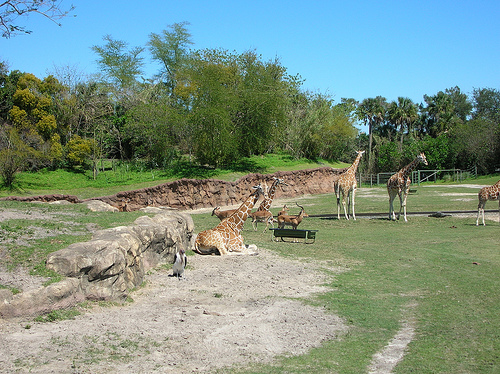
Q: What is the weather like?
A: It is clear.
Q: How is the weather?
A: It is clear.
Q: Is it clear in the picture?
A: Yes, it is clear.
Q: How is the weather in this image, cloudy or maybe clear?
A: It is clear.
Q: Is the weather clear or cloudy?
A: It is clear.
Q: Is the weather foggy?
A: No, it is clear.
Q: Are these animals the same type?
A: Yes, all the animals are giraffes.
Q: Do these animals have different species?
A: No, all the animals are giraffes.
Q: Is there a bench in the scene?
A: Yes, there is a bench.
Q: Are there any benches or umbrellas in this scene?
A: Yes, there is a bench.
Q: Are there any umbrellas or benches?
A: Yes, there is a bench.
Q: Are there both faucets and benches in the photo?
A: No, there is a bench but no faucets.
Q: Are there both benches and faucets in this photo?
A: No, there is a bench but no faucets.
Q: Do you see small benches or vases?
A: Yes, there is a small bench.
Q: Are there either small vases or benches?
A: Yes, there is a small bench.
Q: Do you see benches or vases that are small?
A: Yes, the bench is small.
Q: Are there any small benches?
A: Yes, there is a small bench.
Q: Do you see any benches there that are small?
A: Yes, there is a bench that is small.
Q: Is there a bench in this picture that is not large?
A: Yes, there is a small bench.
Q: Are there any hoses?
A: No, there are no hoses.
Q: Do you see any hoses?
A: No, there are no hoses.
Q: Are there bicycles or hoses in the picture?
A: No, there are no hoses or bicycles.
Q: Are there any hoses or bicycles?
A: No, there are no hoses or bicycles.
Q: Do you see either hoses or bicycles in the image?
A: No, there are no hoses or bicycles.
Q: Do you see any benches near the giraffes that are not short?
A: Yes, there is a bench near the giraffes.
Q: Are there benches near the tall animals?
A: Yes, there is a bench near the giraffes.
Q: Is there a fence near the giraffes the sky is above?
A: No, there is a bench near the giraffes.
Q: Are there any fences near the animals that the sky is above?
A: No, there is a bench near the giraffes.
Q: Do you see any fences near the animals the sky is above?
A: No, there is a bench near the giraffes.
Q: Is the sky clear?
A: Yes, the sky is clear.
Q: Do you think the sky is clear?
A: Yes, the sky is clear.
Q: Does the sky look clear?
A: Yes, the sky is clear.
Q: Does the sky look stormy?
A: No, the sky is clear.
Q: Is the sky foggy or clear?
A: The sky is clear.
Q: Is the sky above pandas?
A: No, the sky is above the giraffes.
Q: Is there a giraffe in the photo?
A: Yes, there are giraffes.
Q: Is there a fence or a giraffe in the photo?
A: Yes, there are giraffes.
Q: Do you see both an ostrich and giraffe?
A: No, there are giraffes but no ostriches.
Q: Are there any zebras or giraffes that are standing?
A: Yes, the giraffes are standing.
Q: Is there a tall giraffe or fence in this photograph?
A: Yes, there are tall giraffes.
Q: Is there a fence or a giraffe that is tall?
A: Yes, the giraffes are tall.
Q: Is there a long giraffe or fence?
A: Yes, there are long giraffes.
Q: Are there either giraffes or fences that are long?
A: Yes, the giraffes are long.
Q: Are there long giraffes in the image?
A: Yes, there are long giraffes.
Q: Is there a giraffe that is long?
A: Yes, there are giraffes that are long.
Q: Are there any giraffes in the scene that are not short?
A: Yes, there are long giraffes.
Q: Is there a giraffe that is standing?
A: Yes, there are giraffes that are standing.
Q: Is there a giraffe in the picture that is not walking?
A: Yes, there are giraffes that are standing.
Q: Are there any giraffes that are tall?
A: Yes, there are tall giraffes.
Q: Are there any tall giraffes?
A: Yes, there are tall giraffes.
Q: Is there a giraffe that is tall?
A: Yes, there are giraffes that are tall.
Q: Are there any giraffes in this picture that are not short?
A: Yes, there are tall giraffes.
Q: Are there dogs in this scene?
A: No, there are no dogs.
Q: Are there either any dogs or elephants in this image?
A: No, there are no dogs or elephants.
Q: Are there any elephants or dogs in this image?
A: No, there are no dogs or elephants.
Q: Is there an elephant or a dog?
A: No, there are no dogs or elephants.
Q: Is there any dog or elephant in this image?
A: No, there are no dogs or elephants.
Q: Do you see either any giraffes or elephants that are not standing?
A: No, there are giraffes but they are standing.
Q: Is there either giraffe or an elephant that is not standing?
A: No, there are giraffes but they are standing.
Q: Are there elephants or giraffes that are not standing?
A: No, there are giraffes but they are standing.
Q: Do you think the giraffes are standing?
A: Yes, the giraffes are standing.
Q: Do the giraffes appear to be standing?
A: Yes, the giraffes are standing.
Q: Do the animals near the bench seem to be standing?
A: Yes, the giraffes are standing.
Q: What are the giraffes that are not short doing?
A: The giraffes are standing.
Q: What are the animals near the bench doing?
A: The giraffes are standing.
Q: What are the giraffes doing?
A: The giraffes are standing.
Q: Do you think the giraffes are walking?
A: No, the giraffes are standing.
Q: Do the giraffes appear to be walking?
A: No, the giraffes are standing.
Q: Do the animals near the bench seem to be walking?
A: No, the giraffes are standing.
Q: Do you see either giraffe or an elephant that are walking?
A: No, there are giraffes but they are standing.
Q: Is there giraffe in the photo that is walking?
A: No, there are giraffes but they are standing.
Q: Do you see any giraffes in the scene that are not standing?
A: No, there are giraffes but they are standing.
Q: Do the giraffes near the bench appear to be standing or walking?
A: The giraffes are standing.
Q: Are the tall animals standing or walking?
A: The giraffes are standing.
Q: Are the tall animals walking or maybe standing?
A: The giraffes are standing.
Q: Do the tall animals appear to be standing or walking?
A: The giraffes are standing.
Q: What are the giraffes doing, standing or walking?
A: The giraffes are standing.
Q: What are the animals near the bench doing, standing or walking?
A: The giraffes are standing.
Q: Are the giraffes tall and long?
A: Yes, the giraffes are tall and long.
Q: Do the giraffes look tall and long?
A: Yes, the giraffes are tall and long.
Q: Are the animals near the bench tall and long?
A: Yes, the giraffes are tall and long.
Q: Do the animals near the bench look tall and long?
A: Yes, the giraffes are tall and long.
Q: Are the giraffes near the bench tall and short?
A: No, the giraffes are tall but long.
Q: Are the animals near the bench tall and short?
A: No, the giraffes are tall but long.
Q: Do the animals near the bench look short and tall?
A: No, the giraffes are tall but long.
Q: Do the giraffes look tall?
A: Yes, the giraffes are tall.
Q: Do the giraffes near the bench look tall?
A: Yes, the giraffes are tall.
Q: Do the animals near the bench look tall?
A: Yes, the giraffes are tall.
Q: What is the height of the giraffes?
A: The giraffes are tall.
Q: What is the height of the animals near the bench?
A: The giraffes are tall.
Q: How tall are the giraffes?
A: The giraffes are tall.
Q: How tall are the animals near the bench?
A: The giraffes are tall.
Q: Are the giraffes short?
A: No, the giraffes are tall.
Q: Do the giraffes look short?
A: No, the giraffes are tall.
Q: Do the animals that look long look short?
A: No, the giraffes are tall.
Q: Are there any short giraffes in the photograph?
A: No, there are giraffes but they are tall.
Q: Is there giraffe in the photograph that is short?
A: No, there are giraffes but they are tall.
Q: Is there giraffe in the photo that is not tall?
A: No, there are giraffes but they are tall.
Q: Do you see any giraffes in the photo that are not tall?
A: No, there are giraffes but they are tall.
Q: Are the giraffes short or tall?
A: The giraffes are tall.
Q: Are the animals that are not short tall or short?
A: The giraffes are tall.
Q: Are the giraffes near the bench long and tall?
A: Yes, the giraffes are long and tall.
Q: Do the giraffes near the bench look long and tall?
A: Yes, the giraffes are long and tall.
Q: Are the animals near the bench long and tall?
A: Yes, the giraffes are long and tall.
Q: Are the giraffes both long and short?
A: No, the giraffes are long but tall.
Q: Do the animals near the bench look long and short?
A: No, the giraffes are long but tall.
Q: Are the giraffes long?
A: Yes, the giraffes are long.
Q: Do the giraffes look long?
A: Yes, the giraffes are long.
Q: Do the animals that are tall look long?
A: Yes, the giraffes are long.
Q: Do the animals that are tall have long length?
A: Yes, the giraffes are long.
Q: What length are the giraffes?
A: The giraffes are long.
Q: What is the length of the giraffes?
A: The giraffes are long.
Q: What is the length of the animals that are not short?
A: The giraffes are long.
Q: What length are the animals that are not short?
A: The giraffes are long.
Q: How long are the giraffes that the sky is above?
A: The giraffes are long.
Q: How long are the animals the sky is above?
A: The giraffes are long.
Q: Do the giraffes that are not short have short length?
A: No, the giraffes are long.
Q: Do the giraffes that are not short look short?
A: No, the giraffes are long.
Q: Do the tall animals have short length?
A: No, the giraffes are long.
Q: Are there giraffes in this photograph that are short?
A: No, there are giraffes but they are long.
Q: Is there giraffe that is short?
A: No, there are giraffes but they are long.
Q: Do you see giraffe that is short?
A: No, there are giraffes but they are long.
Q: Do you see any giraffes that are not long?
A: No, there are giraffes but they are long.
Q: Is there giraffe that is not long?
A: No, there are giraffes but they are long.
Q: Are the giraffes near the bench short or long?
A: The giraffes are long.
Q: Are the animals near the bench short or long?
A: The giraffes are long.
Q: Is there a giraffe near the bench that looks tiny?
A: Yes, there are giraffes near the bench.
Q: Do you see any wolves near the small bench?
A: No, there are giraffes near the bench.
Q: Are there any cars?
A: No, there are no cars.